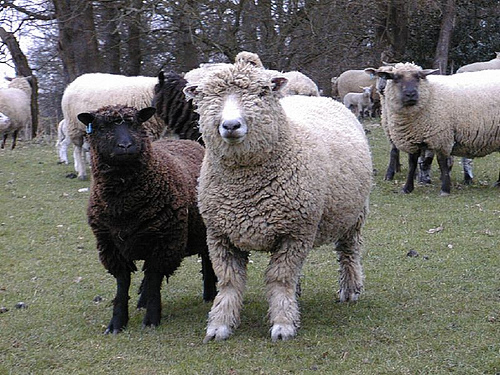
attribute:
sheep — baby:
[338, 82, 375, 120]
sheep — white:
[328, 62, 385, 98]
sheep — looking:
[76, 89, 237, 323]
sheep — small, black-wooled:
[27, 74, 212, 364]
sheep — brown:
[68, 96, 220, 338]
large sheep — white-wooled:
[191, 53, 436, 271]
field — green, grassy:
[0, 244, 487, 368]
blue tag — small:
[80, 120, 94, 144]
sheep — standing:
[382, 62, 497, 193]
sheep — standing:
[76, 105, 198, 328]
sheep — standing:
[62, 72, 152, 109]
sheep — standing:
[335, 69, 372, 88]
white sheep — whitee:
[174, 55, 378, 351]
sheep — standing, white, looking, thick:
[181, 68, 375, 346]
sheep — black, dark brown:
[74, 102, 212, 339]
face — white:
[204, 81, 254, 148]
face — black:
[391, 69, 420, 109]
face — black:
[153, 68, 185, 92]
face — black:
[95, 110, 139, 149]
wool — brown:
[125, 188, 182, 228]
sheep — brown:
[149, 76, 203, 148]